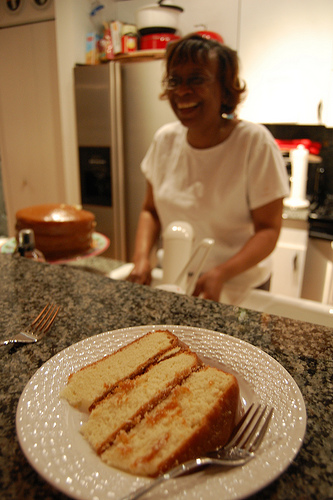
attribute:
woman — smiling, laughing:
[120, 22, 295, 302]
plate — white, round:
[15, 321, 314, 494]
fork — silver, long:
[132, 399, 275, 496]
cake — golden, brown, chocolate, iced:
[59, 323, 251, 486]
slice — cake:
[63, 325, 262, 474]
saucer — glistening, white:
[17, 320, 308, 493]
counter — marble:
[3, 245, 332, 491]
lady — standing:
[122, 27, 290, 300]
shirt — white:
[139, 108, 292, 285]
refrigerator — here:
[71, 59, 169, 261]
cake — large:
[13, 201, 97, 263]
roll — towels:
[284, 145, 314, 209]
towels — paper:
[291, 145, 310, 201]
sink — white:
[105, 221, 332, 337]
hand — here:
[192, 271, 225, 301]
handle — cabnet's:
[291, 252, 301, 273]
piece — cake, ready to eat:
[63, 326, 242, 472]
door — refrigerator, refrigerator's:
[73, 60, 116, 259]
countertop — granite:
[2, 254, 333, 494]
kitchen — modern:
[2, 3, 332, 495]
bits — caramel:
[111, 376, 210, 443]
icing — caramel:
[86, 323, 200, 449]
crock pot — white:
[134, 2, 184, 32]